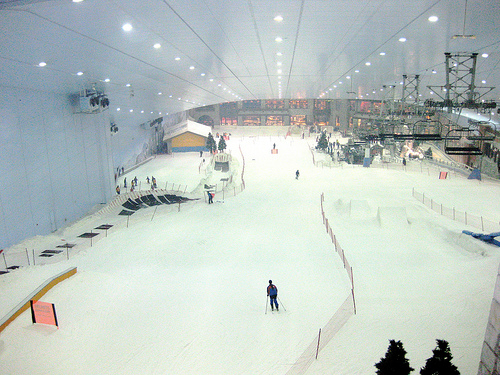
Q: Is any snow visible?
A: Yes, there is snow.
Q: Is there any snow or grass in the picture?
A: Yes, there is snow.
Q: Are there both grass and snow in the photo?
A: No, there is snow but no grass.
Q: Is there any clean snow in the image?
A: Yes, there is clean snow.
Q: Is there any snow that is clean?
A: Yes, there is snow that is clean.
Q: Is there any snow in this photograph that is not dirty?
A: Yes, there is clean snow.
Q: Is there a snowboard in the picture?
A: No, there are no snowboards.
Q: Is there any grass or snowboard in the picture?
A: No, there are no snowboards or grass.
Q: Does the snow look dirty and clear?
A: No, the snow is clear but clean.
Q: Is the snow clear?
A: Yes, the snow is clear.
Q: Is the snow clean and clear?
A: Yes, the snow is clean and clear.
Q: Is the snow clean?
A: Yes, the snow is clean.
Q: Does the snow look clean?
A: Yes, the snow is clean.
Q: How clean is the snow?
A: The snow is clean.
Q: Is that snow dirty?
A: No, the snow is clean.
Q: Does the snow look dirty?
A: No, the snow is clean.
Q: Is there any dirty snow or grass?
A: No, there is snow but it is clean.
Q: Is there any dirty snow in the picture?
A: No, there is snow but it is clean.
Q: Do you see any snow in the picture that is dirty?
A: No, there is snow but it is clean.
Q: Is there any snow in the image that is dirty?
A: No, there is snow but it is clean.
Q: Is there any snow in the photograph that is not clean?
A: No, there is snow but it is clean.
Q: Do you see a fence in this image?
A: Yes, there is a fence.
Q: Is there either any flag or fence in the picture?
A: Yes, there is a fence.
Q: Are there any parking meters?
A: No, there are no parking meters.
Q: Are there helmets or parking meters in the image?
A: No, there are no parking meters or helmets.